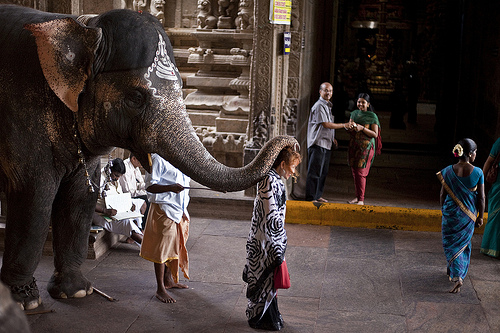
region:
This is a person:
[428, 127, 488, 300]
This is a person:
[343, 85, 393, 216]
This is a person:
[303, 75, 345, 203]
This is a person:
[248, 130, 314, 327]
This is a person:
[142, 113, 205, 313]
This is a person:
[91, 145, 128, 245]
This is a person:
[434, 127, 484, 309]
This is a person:
[480, 121, 499, 275]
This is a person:
[348, 80, 385, 227]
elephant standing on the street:
[3, 0, 305, 332]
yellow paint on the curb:
[261, 186, 485, 248]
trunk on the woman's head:
[239, 134, 311, 188]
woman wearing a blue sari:
[434, 138, 479, 298]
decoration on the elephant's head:
[143, 20, 190, 107]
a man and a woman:
[302, 78, 389, 210]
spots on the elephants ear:
[25, 12, 114, 118]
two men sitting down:
[97, 149, 167, 259]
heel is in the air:
[452, 277, 464, 295]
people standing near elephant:
[90, 59, 474, 303]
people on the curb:
[290, 91, 377, 198]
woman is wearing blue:
[437, 110, 478, 287]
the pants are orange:
[153, 241, 180, 255]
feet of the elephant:
[9, 268, 90, 322]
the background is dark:
[412, 23, 460, 100]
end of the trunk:
[277, 136, 299, 148]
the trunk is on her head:
[266, 127, 303, 184]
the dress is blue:
[448, 213, 464, 230]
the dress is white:
[259, 208, 282, 235]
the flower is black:
[266, 211, 288, 239]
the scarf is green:
[361, 113, 373, 120]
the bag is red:
[276, 268, 287, 280]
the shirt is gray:
[311, 120, 324, 134]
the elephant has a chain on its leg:
[16, 278, 34, 298]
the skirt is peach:
[155, 225, 177, 249]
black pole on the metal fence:
[140, 148, 195, 300]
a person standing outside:
[239, 125, 331, 325]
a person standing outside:
[135, 139, 192, 259]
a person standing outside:
[341, 84, 407, 206]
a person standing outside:
[280, 76, 342, 194]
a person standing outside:
[482, 143, 496, 272]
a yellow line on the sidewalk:
[286, 184, 453, 256]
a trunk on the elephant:
[141, 84, 353, 211]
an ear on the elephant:
[16, 17, 71, 109]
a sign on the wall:
[267, 20, 294, 61]